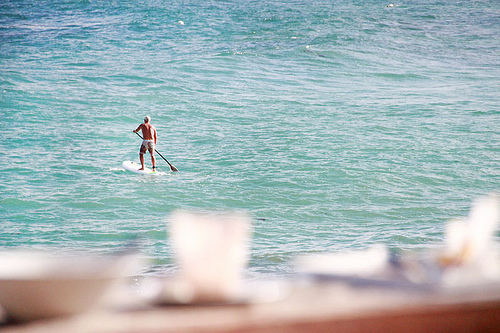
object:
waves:
[36, 41, 353, 111]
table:
[11, 279, 499, 333]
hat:
[143, 116, 151, 123]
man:
[133, 116, 159, 172]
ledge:
[3, 278, 500, 333]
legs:
[139, 143, 148, 167]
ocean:
[2, 0, 499, 275]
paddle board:
[122, 160, 167, 176]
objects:
[0, 190, 499, 332]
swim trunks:
[139, 140, 155, 155]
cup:
[171, 210, 250, 286]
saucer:
[143, 283, 281, 306]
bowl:
[1, 247, 135, 319]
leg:
[148, 146, 156, 168]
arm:
[135, 124, 142, 133]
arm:
[154, 128, 158, 144]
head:
[143, 116, 150, 123]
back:
[141, 123, 155, 140]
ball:
[387, 4, 394, 8]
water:
[1, 1, 499, 278]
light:
[2, 1, 497, 330]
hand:
[132, 130, 135, 134]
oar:
[132, 129, 179, 172]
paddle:
[135, 130, 179, 173]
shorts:
[139, 139, 155, 154]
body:
[132, 115, 158, 171]